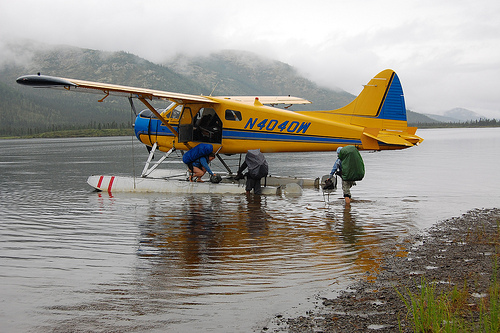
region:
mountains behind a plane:
[1, 30, 486, 214]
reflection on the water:
[54, 215, 359, 317]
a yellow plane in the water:
[6, 53, 438, 207]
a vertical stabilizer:
[345, 63, 414, 118]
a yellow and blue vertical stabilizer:
[346, 64, 418, 121]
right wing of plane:
[220, 78, 312, 109]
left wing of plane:
[18, 68, 211, 109]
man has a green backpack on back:
[325, 135, 370, 210]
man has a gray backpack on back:
[230, 145, 271, 202]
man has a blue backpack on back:
[177, 137, 223, 188]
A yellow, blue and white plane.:
[16, 67, 423, 193]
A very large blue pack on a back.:
[180, 140, 212, 159]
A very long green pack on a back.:
[337, 143, 367, 183]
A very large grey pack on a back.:
[243, 145, 270, 177]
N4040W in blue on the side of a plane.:
[243, 115, 312, 135]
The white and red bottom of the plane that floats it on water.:
[85, 165, 320, 198]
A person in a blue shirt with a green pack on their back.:
[325, 142, 365, 206]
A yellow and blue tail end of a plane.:
[350, 66, 408, 123]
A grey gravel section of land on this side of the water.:
[288, 205, 495, 329]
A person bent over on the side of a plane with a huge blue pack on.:
[183, 136, 219, 185]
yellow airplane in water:
[81, 37, 358, 191]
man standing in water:
[251, 142, 284, 203]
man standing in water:
[327, 135, 365, 197]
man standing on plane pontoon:
[164, 106, 230, 189]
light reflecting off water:
[69, 198, 266, 329]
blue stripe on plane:
[227, 127, 324, 151]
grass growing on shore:
[408, 280, 469, 332]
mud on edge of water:
[372, 171, 494, 306]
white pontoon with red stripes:
[91, 162, 244, 209]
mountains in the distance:
[74, 56, 321, 164]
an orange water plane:
[15, 62, 424, 209]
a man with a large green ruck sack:
[325, 145, 367, 202]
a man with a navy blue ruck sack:
[231, 145, 273, 197]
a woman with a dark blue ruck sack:
[179, 135, 220, 182]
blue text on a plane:
[241, 113, 318, 134]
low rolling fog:
[0, 0, 485, 74]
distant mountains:
[0, 37, 310, 89]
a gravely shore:
[306, 208, 497, 328]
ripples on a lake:
[3, 219, 270, 319]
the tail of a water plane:
[345, 71, 416, 127]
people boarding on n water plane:
[16, 69, 420, 219]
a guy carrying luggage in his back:
[320, 145, 360, 200]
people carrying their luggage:
[180, 140, 360, 200]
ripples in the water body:
[0, 187, 420, 297]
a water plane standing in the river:
[13, 65, 435, 233]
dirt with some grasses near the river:
[275, 202, 495, 329]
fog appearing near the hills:
[1, 35, 342, 96]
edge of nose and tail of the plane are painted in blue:
[130, 68, 416, 169]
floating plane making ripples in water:
[8, 68, 423, 248]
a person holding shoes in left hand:
[323, 145, 365, 209]